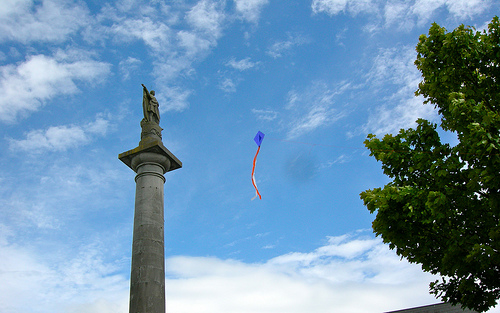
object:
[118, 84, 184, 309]
tower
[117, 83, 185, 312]
pole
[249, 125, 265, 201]
kite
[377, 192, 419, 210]
leaf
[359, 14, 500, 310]
tall tree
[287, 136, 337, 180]
blue sky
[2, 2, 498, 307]
clouds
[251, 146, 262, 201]
tail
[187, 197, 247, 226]
blue sky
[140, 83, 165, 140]
statue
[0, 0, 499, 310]
sky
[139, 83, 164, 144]
water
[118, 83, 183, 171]
figure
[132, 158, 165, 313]
pillar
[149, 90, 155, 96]
head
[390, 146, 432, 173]
leaf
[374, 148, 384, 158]
leaf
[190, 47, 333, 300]
air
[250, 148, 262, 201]
string